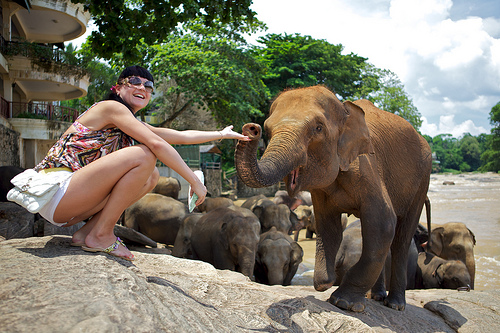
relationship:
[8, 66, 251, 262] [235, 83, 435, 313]
woman close to elephant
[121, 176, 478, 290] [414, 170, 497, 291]
elephants near river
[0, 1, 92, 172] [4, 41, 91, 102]
balcony with building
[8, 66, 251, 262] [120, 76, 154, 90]
woman wearing sunglasses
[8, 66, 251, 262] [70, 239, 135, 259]
woman wearing flip flops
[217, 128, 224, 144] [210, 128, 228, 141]
bracelet on wrist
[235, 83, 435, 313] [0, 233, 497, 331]
elephant on rock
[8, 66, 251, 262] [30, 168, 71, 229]
woman wearing shorts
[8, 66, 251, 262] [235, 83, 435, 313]
woman touching elephant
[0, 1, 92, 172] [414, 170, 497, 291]
balcony by river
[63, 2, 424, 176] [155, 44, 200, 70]
trees with leaves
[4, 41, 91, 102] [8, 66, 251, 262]
building behind woman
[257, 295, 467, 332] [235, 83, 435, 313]
shadow of elephant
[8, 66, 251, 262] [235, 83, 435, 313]
woman feeding elephant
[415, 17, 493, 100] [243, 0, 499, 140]
clouds in sky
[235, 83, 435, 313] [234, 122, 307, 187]
elephant has nose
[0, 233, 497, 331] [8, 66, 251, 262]
rock under woman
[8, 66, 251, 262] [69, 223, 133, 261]
woman has feet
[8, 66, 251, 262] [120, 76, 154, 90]
woman has sunglasses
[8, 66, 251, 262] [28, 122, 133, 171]
woman has top